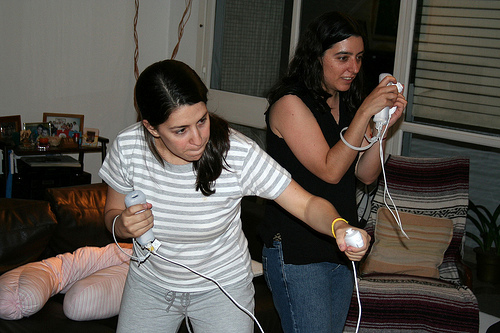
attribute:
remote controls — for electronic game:
[92, 170, 391, 325]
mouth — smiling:
[338, 75, 356, 84]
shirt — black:
[256, 83, 361, 270]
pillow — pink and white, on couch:
[0, 239, 142, 322]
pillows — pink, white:
[2, 235, 127, 322]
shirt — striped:
[105, 117, 285, 291]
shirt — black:
[271, 92, 369, 261]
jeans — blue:
[261, 230, 359, 332]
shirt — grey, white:
[74, 116, 295, 288]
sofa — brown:
[1, 158, 99, 279]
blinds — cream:
[381, 11, 495, 129]